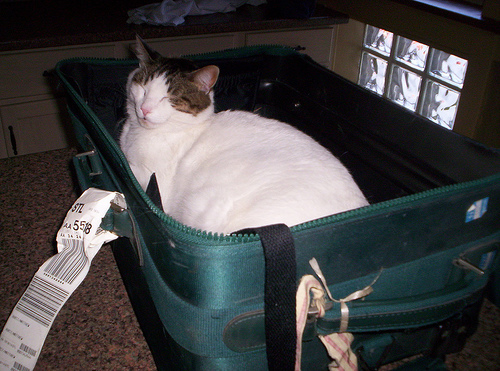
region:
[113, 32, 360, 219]
a fat cat doses in a blue suitcase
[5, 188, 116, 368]
a black and white baggage tag hangs off a blue suitcase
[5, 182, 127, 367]
a claim ticket taped on the handle of a bag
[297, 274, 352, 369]
a faded pink and white ribbon sticks to a suitcase handle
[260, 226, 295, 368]
a dark blue strap dangles outside a valise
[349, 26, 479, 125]
light shines through a small multi-paned window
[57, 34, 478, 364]
a large blue suitcase sits on the floor next to a six paned window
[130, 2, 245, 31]
a white t-shirt laying on a granite counter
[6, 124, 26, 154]
a black handle on a whit wood cabinet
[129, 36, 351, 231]
a fluff white and brown sleeps in a large suitcase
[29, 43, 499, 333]
a cat sleeping in a suitcase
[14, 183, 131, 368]
an airline luggage tag on a suitcase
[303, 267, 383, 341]
a faded yellow ribbon on the suitcase handle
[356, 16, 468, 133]
a glass block window in the room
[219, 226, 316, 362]
a black strap coming out of the suitcase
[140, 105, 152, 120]
a small pink nose on the cat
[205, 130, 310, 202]
all white fur on the sleeping cat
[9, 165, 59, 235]
a granite counter top the suitcase is on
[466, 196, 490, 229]
a tsa sticker on the top of the suitcase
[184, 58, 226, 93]
a small pink hairy ear on the cat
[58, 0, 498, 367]
the cat is in a suitcase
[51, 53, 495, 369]
the suitcase is green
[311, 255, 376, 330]
the suitcase has a ribbon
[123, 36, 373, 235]
the cat is white and brown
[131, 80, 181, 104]
the cat's eyes are closed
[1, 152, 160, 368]
the floor is carpeted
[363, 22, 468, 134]
the wall is made of glass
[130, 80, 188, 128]
the cat is smiling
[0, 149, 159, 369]
the floor is brown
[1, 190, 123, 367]
the luggage has a tag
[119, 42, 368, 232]
brown black and white kitty sitting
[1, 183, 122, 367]
paper luggage tag with black text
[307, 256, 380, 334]
identifier ribbon tied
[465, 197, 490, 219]
blue white small sticker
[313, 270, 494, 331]
dark green luggage handle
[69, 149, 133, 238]
dark green luggage handle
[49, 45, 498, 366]
dark green luggage open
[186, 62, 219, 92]
large pink cat ear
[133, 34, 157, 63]
large pink and brown cat ear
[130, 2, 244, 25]
white piece of cloth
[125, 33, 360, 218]
a cat sleeping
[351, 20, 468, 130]
six glass windows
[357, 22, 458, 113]
very thick windows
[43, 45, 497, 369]
a cat in a suitcase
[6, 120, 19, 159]
a little handle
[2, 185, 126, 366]
a white piece of paper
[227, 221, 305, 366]
a dark blue strap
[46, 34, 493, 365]
suitcase filled with a sleeping cat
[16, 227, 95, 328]
two different bar codes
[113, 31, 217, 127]
a cat with its eyes closed